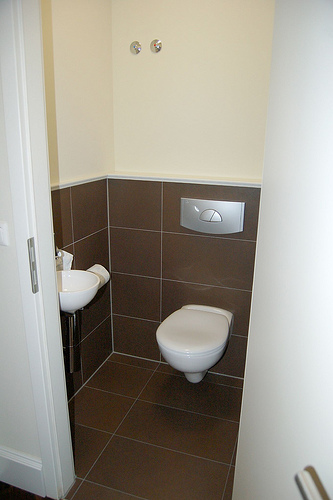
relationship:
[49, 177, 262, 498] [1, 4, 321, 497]
tile on bathroom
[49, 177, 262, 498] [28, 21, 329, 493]
tile on bathroom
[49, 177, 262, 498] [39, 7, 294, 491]
tile on bathroom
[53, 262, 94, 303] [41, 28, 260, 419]
sink on bathroom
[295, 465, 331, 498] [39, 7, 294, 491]
doorknob on bathroom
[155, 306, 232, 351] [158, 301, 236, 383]
lid on toilet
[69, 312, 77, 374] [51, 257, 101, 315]
pipe on sink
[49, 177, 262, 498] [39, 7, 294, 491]
tile in bathroom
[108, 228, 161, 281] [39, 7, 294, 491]
tile in bathroom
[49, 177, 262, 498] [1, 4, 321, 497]
tile in bathroom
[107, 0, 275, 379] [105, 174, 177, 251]
wall made tile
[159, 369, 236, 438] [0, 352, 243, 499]
shadow on floor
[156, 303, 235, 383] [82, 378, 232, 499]
procelain toilet over floor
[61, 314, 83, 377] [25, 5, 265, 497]
pipe in bathroom